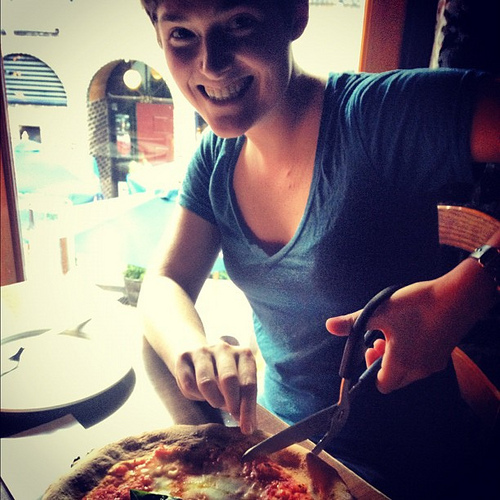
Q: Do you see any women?
A: Yes, there is a woman.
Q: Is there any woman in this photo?
A: Yes, there is a woman.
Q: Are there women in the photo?
A: Yes, there is a woman.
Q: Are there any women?
A: Yes, there is a woman.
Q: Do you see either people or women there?
A: Yes, there is a woman.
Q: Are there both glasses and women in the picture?
A: No, there is a woman but no glasses.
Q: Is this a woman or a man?
A: This is a woman.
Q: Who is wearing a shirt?
A: The woman is wearing a shirt.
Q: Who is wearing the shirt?
A: The woman is wearing a shirt.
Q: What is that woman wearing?
A: The woman is wearing a shirt.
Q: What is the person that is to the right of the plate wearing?
A: The woman is wearing a shirt.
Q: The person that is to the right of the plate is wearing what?
A: The woman is wearing a shirt.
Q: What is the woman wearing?
A: The woman is wearing a shirt.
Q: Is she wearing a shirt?
A: Yes, the woman is wearing a shirt.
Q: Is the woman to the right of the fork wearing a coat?
A: No, the woman is wearing a shirt.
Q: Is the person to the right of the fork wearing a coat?
A: No, the woman is wearing a shirt.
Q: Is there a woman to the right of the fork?
A: Yes, there is a woman to the right of the fork.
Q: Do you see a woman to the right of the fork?
A: Yes, there is a woman to the right of the fork.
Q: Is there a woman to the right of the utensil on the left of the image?
A: Yes, there is a woman to the right of the fork.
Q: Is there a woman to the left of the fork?
A: No, the woman is to the right of the fork.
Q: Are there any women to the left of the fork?
A: No, the woman is to the right of the fork.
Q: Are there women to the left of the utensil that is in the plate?
A: No, the woman is to the right of the fork.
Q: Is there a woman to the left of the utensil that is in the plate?
A: No, the woman is to the right of the fork.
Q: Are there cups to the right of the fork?
A: No, there is a woman to the right of the fork.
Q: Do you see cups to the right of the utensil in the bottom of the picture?
A: No, there is a woman to the right of the fork.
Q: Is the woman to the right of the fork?
A: Yes, the woman is to the right of the fork.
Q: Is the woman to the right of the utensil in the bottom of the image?
A: Yes, the woman is to the right of the fork.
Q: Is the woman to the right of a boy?
A: No, the woman is to the right of the fork.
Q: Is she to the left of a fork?
A: No, the woman is to the right of a fork.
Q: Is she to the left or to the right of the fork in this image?
A: The woman is to the right of the fork.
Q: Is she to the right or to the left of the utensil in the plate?
A: The woman is to the right of the fork.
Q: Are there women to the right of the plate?
A: Yes, there is a woman to the right of the plate.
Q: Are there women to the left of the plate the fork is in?
A: No, the woman is to the right of the plate.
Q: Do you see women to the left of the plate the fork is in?
A: No, the woman is to the right of the plate.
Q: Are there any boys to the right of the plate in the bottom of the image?
A: No, there is a woman to the right of the plate.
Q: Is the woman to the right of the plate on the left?
A: Yes, the woman is to the right of the plate.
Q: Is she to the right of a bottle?
A: No, the woman is to the right of the plate.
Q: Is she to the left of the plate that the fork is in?
A: No, the woman is to the right of the plate.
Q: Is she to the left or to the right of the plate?
A: The woman is to the right of the plate.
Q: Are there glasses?
A: No, there are no glasses.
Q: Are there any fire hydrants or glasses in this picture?
A: No, there are no glasses or fire hydrants.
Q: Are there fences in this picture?
A: No, there are no fences.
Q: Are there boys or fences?
A: No, there are no fences or boys.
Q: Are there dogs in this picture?
A: No, there are no dogs.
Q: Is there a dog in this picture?
A: No, there are no dogs.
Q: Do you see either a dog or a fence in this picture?
A: No, there are no dogs or fences.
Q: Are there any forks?
A: Yes, there is a fork.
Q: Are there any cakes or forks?
A: Yes, there is a fork.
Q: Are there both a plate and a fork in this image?
A: Yes, there are both a fork and a plate.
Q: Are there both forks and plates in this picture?
A: Yes, there are both a fork and a plate.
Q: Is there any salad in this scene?
A: No, there is no salad.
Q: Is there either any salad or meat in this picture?
A: No, there are no salad or meat.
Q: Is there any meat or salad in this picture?
A: No, there are no salad or meat.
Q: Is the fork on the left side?
A: Yes, the fork is on the left of the image.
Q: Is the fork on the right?
A: No, the fork is on the left of the image.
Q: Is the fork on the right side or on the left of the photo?
A: The fork is on the left of the image.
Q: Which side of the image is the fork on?
A: The fork is on the left of the image.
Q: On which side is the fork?
A: The fork is on the left of the image.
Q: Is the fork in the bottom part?
A: Yes, the fork is in the bottom of the image.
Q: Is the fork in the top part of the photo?
A: No, the fork is in the bottom of the image.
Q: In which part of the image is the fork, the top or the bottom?
A: The fork is in the bottom of the image.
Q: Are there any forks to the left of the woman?
A: Yes, there is a fork to the left of the woman.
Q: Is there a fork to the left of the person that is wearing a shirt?
A: Yes, there is a fork to the left of the woman.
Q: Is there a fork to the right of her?
A: No, the fork is to the left of the woman.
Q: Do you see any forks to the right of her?
A: No, the fork is to the left of the woman.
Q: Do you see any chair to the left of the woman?
A: No, there is a fork to the left of the woman.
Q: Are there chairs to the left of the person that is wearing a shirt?
A: No, there is a fork to the left of the woman.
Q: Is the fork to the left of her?
A: Yes, the fork is to the left of the woman.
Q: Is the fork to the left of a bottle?
A: No, the fork is to the left of the woman.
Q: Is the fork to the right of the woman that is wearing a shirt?
A: No, the fork is to the left of the woman.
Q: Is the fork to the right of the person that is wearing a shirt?
A: No, the fork is to the left of the woman.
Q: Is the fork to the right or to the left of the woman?
A: The fork is to the left of the woman.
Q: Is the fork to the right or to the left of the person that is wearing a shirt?
A: The fork is to the left of the woman.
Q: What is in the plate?
A: The fork is in the plate.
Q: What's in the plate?
A: The fork is in the plate.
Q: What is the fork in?
A: The fork is in the plate.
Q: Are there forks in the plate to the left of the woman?
A: Yes, there is a fork in the plate.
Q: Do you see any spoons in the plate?
A: No, there is a fork in the plate.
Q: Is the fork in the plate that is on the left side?
A: Yes, the fork is in the plate.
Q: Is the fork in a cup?
A: No, the fork is in the plate.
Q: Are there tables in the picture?
A: Yes, there is a table.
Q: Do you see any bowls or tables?
A: Yes, there is a table.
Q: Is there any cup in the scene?
A: No, there are no cups.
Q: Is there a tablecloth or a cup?
A: No, there are no cups or tablecloths.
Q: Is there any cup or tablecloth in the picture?
A: No, there are no cups or tablecloths.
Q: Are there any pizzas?
A: Yes, there is a pizza.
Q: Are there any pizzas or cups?
A: Yes, there is a pizza.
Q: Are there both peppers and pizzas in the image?
A: No, there is a pizza but no peppers.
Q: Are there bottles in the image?
A: No, there are no bottles.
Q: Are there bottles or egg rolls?
A: No, there are no bottles or egg rolls.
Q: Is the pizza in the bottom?
A: Yes, the pizza is in the bottom of the image.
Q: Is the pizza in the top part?
A: No, the pizza is in the bottom of the image.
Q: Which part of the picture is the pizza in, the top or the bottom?
A: The pizza is in the bottom of the image.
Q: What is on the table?
A: The pizza is on the table.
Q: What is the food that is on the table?
A: The food is a pizza.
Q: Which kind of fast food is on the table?
A: The food is a pizza.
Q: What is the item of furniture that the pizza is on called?
A: The piece of furniture is a table.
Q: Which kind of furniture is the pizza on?
A: The pizza is on the table.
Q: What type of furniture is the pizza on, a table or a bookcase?
A: The pizza is on a table.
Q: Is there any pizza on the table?
A: Yes, there is a pizza on the table.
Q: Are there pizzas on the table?
A: Yes, there is a pizza on the table.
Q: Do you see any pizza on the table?
A: Yes, there is a pizza on the table.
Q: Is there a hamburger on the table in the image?
A: No, there is a pizza on the table.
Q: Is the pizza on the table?
A: Yes, the pizza is on the table.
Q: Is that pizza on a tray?
A: No, the pizza is on the table.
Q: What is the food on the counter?
A: The food is a pizza.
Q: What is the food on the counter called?
A: The food is a pizza.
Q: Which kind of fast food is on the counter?
A: The food is a pizza.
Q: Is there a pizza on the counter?
A: Yes, there is a pizza on the counter.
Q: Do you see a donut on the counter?
A: No, there is a pizza on the counter.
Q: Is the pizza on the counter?
A: Yes, the pizza is on the counter.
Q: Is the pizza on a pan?
A: No, the pizza is on the counter.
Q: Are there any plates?
A: Yes, there is a plate.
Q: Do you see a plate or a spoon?
A: Yes, there is a plate.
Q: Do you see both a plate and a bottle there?
A: No, there is a plate but no bottles.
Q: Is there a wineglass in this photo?
A: No, there are no wine glasses.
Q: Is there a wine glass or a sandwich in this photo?
A: No, there are no wine glasses or sandwiches.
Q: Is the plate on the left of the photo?
A: Yes, the plate is on the left of the image.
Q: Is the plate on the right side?
A: No, the plate is on the left of the image.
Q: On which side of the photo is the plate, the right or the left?
A: The plate is on the left of the image.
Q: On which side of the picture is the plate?
A: The plate is on the left of the image.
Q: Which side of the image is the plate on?
A: The plate is on the left of the image.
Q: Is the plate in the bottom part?
A: Yes, the plate is in the bottom of the image.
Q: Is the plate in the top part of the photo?
A: No, the plate is in the bottom of the image.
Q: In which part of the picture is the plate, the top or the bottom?
A: The plate is in the bottom of the image.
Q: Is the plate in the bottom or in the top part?
A: The plate is in the bottom of the image.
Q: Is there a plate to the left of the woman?
A: Yes, there is a plate to the left of the woman.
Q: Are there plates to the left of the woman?
A: Yes, there is a plate to the left of the woman.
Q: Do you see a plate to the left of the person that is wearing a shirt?
A: Yes, there is a plate to the left of the woman.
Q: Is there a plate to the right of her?
A: No, the plate is to the left of the woman.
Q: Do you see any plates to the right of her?
A: No, the plate is to the left of the woman.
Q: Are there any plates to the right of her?
A: No, the plate is to the left of the woman.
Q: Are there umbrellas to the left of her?
A: No, there is a plate to the left of the woman.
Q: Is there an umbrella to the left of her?
A: No, there is a plate to the left of the woman.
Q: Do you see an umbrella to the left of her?
A: No, there is a plate to the left of the woman.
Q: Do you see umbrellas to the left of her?
A: No, there is a plate to the left of the woman.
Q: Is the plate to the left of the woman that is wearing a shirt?
A: Yes, the plate is to the left of the woman.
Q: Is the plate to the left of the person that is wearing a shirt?
A: Yes, the plate is to the left of the woman.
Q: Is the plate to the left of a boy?
A: No, the plate is to the left of the woman.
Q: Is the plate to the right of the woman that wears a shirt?
A: No, the plate is to the left of the woman.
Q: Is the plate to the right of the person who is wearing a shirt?
A: No, the plate is to the left of the woman.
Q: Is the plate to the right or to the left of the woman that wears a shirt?
A: The plate is to the left of the woman.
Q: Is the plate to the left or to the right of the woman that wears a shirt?
A: The plate is to the left of the woman.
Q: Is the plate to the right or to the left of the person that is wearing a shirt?
A: The plate is to the left of the woman.